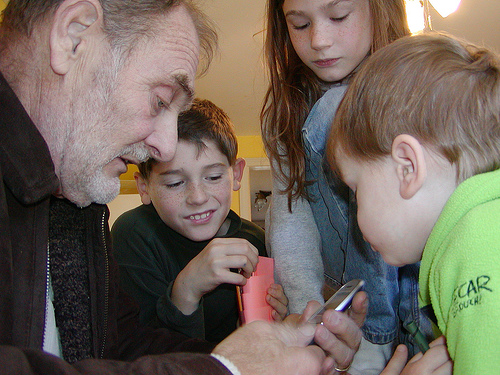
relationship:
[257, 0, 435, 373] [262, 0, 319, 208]
girl has brown hair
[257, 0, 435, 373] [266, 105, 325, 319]
girl wearing sweatshirt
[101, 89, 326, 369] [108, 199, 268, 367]
boy wearing shirt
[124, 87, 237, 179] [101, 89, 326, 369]
hair of boy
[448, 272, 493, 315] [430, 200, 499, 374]
lettering on sleeve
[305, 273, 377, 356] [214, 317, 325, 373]
phone in hand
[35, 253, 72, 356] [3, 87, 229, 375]
shirt under coat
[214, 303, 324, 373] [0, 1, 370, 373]
hand of man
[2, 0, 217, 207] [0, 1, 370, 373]
head of man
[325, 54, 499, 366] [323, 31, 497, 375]
head of boy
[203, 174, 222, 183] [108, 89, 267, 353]
eye of boy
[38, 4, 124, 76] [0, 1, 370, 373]
ear of man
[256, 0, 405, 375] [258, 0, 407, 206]
girl has brown hair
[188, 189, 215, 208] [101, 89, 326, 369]
nose on boy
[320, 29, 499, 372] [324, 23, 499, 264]
boy has hair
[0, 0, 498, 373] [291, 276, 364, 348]
family looking at phone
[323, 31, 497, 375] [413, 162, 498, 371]
boy wearing sweater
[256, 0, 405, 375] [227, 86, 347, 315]
girl has sweater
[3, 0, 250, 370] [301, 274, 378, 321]
man holding phone